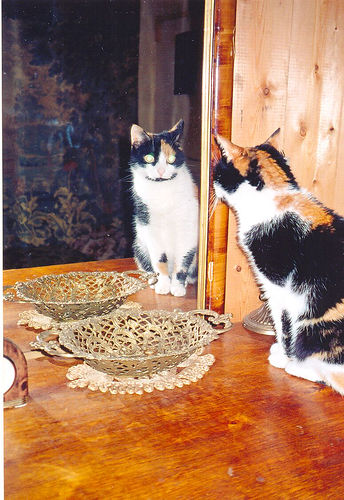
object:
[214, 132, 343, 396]
cat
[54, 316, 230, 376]
basket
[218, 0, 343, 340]
wall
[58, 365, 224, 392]
coaster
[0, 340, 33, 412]
clock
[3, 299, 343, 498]
dresser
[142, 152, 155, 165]
eyes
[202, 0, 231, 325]
frame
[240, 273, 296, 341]
lamp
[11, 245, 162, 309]
reflection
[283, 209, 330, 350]
fur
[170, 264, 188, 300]
front paws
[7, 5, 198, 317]
mirror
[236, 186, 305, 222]
neck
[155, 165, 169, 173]
nose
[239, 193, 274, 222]
white fur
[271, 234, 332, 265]
black fur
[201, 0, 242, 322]
trim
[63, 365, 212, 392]
doiley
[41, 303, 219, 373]
bowl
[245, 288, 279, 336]
candle stick